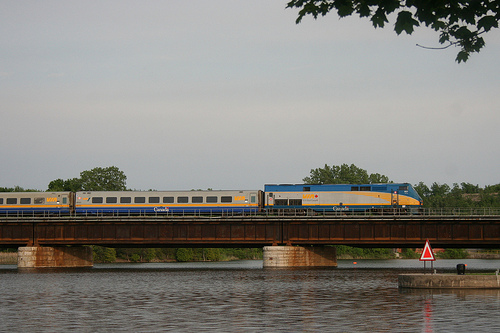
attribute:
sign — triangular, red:
[420, 241, 437, 275]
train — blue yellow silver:
[3, 181, 429, 211]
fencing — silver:
[1, 208, 499, 220]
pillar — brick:
[263, 242, 338, 271]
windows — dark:
[89, 195, 235, 207]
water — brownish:
[156, 278, 364, 320]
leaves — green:
[294, 2, 489, 38]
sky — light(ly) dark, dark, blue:
[136, 32, 308, 152]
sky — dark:
[103, 24, 259, 142]